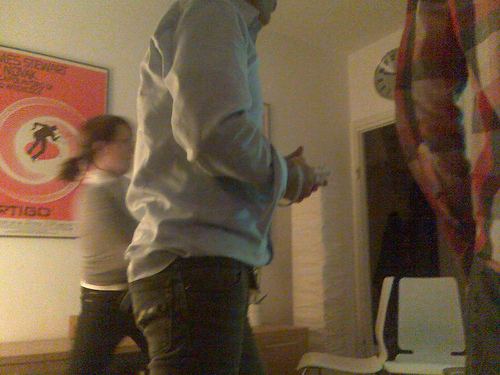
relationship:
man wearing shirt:
[104, 74, 256, 270] [68, 151, 190, 296]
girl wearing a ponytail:
[57, 114, 152, 375] [52, 153, 85, 187]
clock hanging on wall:
[373, 49, 405, 103] [303, 52, 354, 145]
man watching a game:
[397, 0, 500, 373] [273, 126, 363, 203]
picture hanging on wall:
[0, 43, 109, 237] [0, 3, 296, 342]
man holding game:
[121, 0, 328, 375] [274, 164, 331, 208]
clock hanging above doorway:
[373, 48, 402, 101] [349, 114, 454, 348]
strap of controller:
[278, 160, 303, 207] [308, 162, 335, 184]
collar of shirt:
[84, 163, 119, 195] [76, 166, 132, 291]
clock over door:
[373, 48, 402, 101] [360, 122, 437, 345]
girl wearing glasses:
[57, 114, 152, 375] [101, 132, 154, 151]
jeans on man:
[151, 228, 263, 374] [121, 0, 328, 375]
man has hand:
[121, 0, 328, 375] [283, 141, 328, 202]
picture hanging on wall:
[0, 43, 109, 237] [3, 2, 138, 271]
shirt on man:
[393, 1, 498, 274] [397, 4, 499, 373]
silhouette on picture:
[26, 122, 58, 160] [0, 43, 109, 237]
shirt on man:
[99, 31, 309, 307] [129, 2, 288, 354]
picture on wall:
[0, 43, 109, 237] [1, 3, 127, 261]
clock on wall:
[373, 48, 402, 101] [304, 15, 410, 122]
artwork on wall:
[1, 43, 114, 251] [2, 3, 124, 283]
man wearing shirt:
[121, 0, 328, 375] [124, 0, 288, 282]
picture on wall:
[0, 43, 119, 237] [1, 0, 466, 358]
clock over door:
[373, 48, 402, 101] [359, 125, 406, 272]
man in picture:
[22, 117, 64, 161] [0, 43, 119, 237]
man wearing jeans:
[121, 0, 328, 375] [123, 243, 263, 370]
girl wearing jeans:
[57, 114, 152, 375] [58, 269, 136, 365]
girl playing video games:
[51, 108, 155, 372] [233, 118, 414, 275]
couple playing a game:
[50, 5, 312, 372] [290, 106, 467, 328]